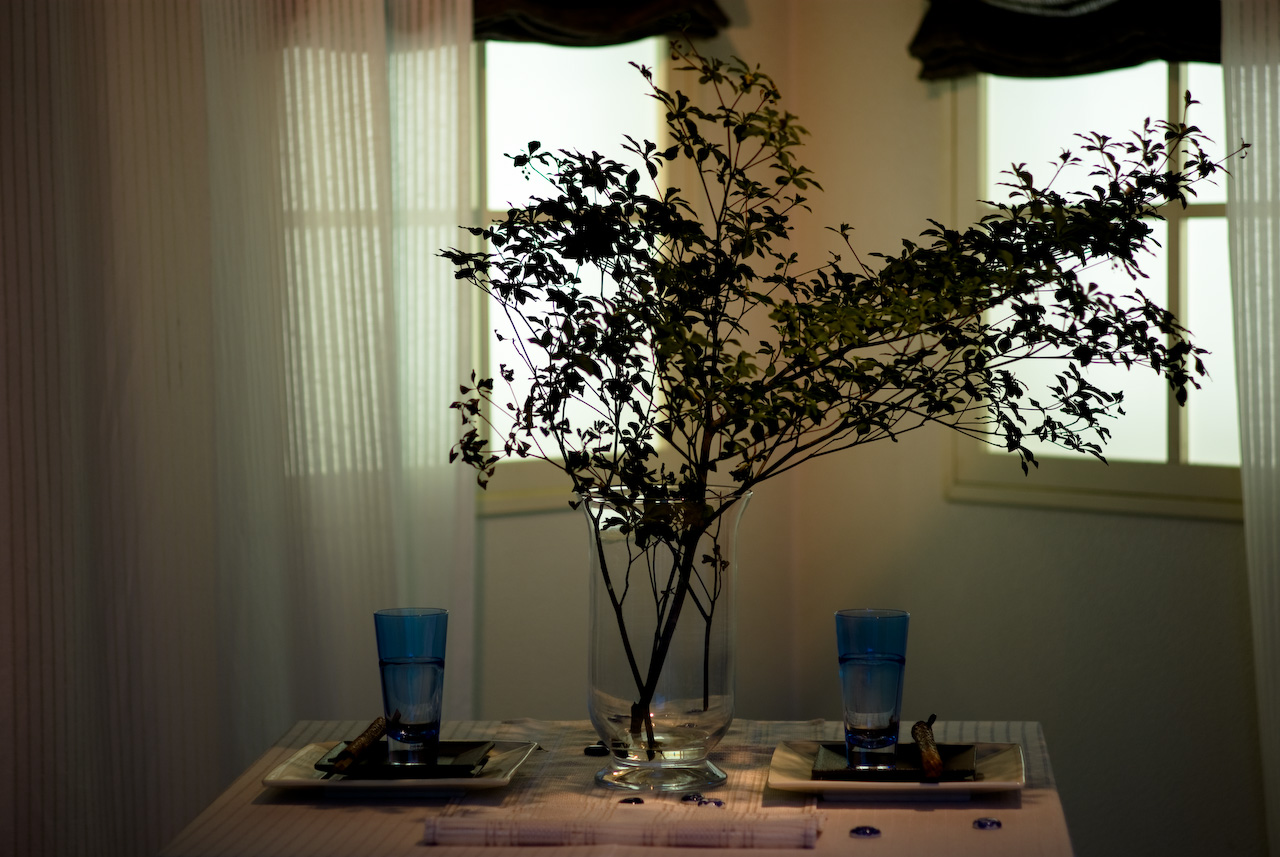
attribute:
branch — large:
[440, 42, 1235, 758]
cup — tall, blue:
[374, 603, 447, 754]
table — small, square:
[184, 707, 1065, 855]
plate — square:
[811, 733, 979, 787]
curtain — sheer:
[9, 7, 499, 855]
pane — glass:
[281, 18, 474, 213]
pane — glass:
[266, 221, 483, 480]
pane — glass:
[491, 230, 673, 454]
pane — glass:
[482, 34, 674, 224]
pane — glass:
[947, 27, 1179, 211]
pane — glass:
[1175, 36, 1277, 220]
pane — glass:
[983, 210, 1171, 466]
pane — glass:
[1181, 204, 1257, 481]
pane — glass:
[802, 589, 919, 742]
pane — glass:
[935, 11, 1242, 517]